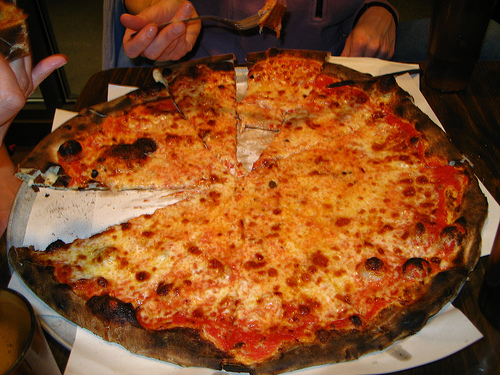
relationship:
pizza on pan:
[45, 92, 248, 189] [27, 183, 154, 271]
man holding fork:
[108, 0, 409, 77] [158, 0, 275, 32]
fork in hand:
[158, 0, 275, 32] [111, 3, 208, 64]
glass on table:
[6, 289, 60, 374] [8, 94, 493, 374]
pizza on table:
[9, 49, 487, 374] [76, 68, 497, 374]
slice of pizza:
[147, 54, 273, 165] [9, 49, 487, 374]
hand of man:
[115, 2, 204, 60] [232, 0, 310, 43]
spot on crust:
[87, 285, 143, 332] [19, 37, 484, 372]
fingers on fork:
[121, 4, 198, 61] [127, 7, 273, 37]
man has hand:
[112, 0, 409, 73] [113, 0, 209, 61]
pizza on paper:
[9, 49, 487, 374] [338, 51, 421, 81]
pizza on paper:
[9, 49, 487, 374] [64, 342, 175, 373]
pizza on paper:
[9, 49, 487, 374] [367, 305, 492, 370]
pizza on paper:
[9, 49, 487, 374] [31, 190, 150, 232]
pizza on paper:
[9, 49, 487, 374] [106, 82, 129, 98]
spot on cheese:
[134, 138, 156, 152] [44, 56, 462, 361]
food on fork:
[252, 0, 290, 35] [127, 6, 282, 31]